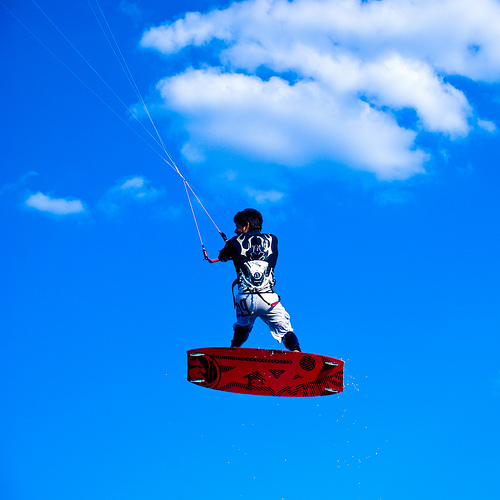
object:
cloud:
[19, 188, 87, 222]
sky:
[0, 0, 499, 203]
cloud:
[151, 66, 433, 186]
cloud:
[250, 2, 498, 80]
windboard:
[186, 345, 345, 401]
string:
[23, 2, 229, 252]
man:
[218, 208, 303, 356]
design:
[196, 353, 219, 392]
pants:
[233, 289, 299, 346]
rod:
[198, 232, 231, 266]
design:
[235, 234, 274, 283]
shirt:
[214, 233, 280, 290]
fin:
[190, 351, 208, 362]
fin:
[190, 375, 208, 387]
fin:
[322, 358, 341, 370]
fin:
[321, 383, 341, 397]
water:
[339, 350, 364, 398]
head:
[231, 208, 266, 237]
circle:
[297, 353, 318, 374]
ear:
[241, 219, 251, 235]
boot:
[281, 331, 304, 353]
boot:
[228, 324, 253, 348]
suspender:
[231, 277, 282, 311]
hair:
[242, 210, 259, 220]